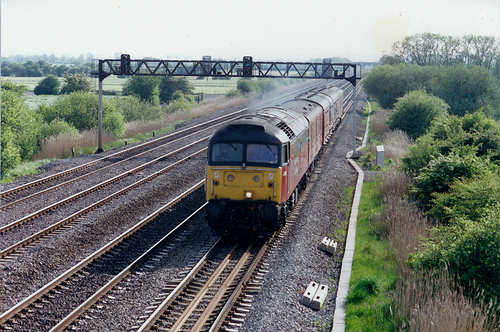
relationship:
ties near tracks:
[298, 275, 328, 315] [7, 150, 197, 330]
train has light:
[204, 78, 353, 241] [242, 187, 257, 203]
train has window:
[204, 78, 353, 241] [244, 143, 280, 169]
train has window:
[204, 78, 353, 241] [208, 139, 247, 167]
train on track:
[204, 78, 353, 241] [135, 222, 280, 330]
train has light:
[204, 78, 353, 241] [238, 189, 255, 204]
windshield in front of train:
[207, 138, 282, 168] [204, 78, 353, 241]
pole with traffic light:
[89, 54, 359, 84] [116, 49, 134, 82]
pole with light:
[89, 54, 359, 84] [241, 57, 253, 77]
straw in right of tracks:
[379, 118, 479, 330] [130, 225, 280, 330]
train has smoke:
[199, 78, 353, 241] [248, 74, 309, 108]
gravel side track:
[288, 238, 320, 272] [62, 222, 276, 331]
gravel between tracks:
[132, 253, 182, 287] [75, 229, 262, 330]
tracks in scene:
[6, 89, 342, 318] [1, 7, 491, 321]